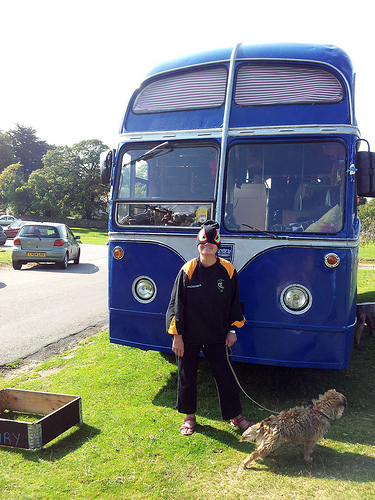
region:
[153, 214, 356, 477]
a person wearing a custom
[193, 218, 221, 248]
a mask the person is wearing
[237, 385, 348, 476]
a dog on leash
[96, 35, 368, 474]
a person wearing a costume next to the blue bus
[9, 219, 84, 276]
a car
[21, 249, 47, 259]
a yellow plate number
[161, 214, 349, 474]
a person with a dog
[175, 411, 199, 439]
a sandal a person is wearing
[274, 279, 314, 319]
a light on the bus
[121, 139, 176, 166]
a wiper of a bus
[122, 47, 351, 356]
the bus is blue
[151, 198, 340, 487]
a person holding a leash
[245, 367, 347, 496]
the dog is wearing collar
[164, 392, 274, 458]
the sandals has red straps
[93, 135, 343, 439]
the bus is parked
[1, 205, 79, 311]
car on the street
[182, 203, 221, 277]
the person is wearing a mask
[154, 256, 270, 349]
the jacket is black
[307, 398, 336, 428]
the collar is red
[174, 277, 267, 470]
the pants are red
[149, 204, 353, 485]
a person with a dog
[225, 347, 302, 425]
leash of a dog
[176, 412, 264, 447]
red sandles on feet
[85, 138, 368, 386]
front of a blue bus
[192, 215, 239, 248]
black hat with eyes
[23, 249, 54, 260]
yellow and black license plate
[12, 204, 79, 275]
a silver car on the road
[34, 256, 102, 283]
shadow of car on the road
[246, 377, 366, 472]
a brown shaggy dog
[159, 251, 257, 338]
a black and yellow shirt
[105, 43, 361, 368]
blue and gray front of bus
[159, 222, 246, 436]
black and orange man standing in grass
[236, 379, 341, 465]
small brown dog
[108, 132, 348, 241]
two big windshields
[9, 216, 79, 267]
gray car rolling in the street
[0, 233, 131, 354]
gray pavement road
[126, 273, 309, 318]
two front lights of blue bus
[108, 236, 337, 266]
two orange lights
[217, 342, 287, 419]
rope holding the dog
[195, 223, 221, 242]
black and orange helmet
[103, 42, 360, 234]
Blue bus with sleeper cab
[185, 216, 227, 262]
Woman wearing funny ski cap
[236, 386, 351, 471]
Brown dog with red collar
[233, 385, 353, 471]
Shaggy dog on leash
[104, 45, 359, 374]
Female posing in front of bus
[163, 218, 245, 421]
Woman wearing black and yellow athletic outfit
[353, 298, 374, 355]
Individual looking under bus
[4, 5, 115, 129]
Clear sunny sky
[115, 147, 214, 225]
Open front window on bus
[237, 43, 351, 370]
Large blue and white bus